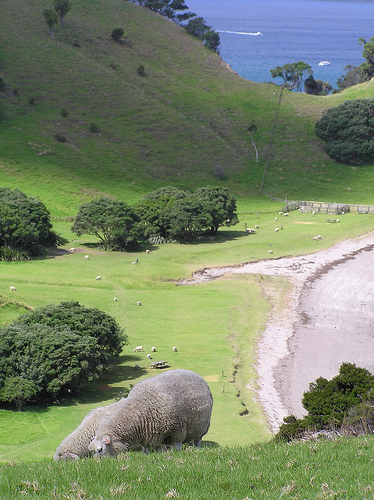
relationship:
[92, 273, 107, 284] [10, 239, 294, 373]
sheep in pasteur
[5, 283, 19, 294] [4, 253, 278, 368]
sheep in pasteur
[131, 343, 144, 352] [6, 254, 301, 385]
sheep in pasteur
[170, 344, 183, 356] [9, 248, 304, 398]
sheep in pasteur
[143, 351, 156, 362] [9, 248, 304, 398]
sheep in pasteur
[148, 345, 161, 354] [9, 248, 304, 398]
sheep in pasteur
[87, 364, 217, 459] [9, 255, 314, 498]
sheep in pasteur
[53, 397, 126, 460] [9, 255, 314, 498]
sheep in pasteur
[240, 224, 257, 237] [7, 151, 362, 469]
sheep in pasteur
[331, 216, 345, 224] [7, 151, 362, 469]
sheep in pasteur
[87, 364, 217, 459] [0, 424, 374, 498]
sheep grazing in hill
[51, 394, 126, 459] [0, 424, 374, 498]
sheep grazing in hill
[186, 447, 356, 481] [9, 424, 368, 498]
grass on hill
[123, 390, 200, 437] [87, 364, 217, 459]
coat on sheep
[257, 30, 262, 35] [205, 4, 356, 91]
boat on water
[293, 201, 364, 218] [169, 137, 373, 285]
sheep in field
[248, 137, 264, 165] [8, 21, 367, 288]
log in field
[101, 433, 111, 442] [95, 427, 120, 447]
indentification tag on sheep's ear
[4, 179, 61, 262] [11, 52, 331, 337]
tree in field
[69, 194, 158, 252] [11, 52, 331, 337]
tree in field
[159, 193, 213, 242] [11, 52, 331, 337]
tree in field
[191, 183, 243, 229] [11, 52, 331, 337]
tree in field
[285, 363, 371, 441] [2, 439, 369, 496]
tree on hill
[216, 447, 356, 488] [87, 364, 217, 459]
grass near sheep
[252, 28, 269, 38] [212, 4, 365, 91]
boat on water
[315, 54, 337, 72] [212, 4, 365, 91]
boat on water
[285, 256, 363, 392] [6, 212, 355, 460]
sand near fields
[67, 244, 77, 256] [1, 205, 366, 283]
sheep in field